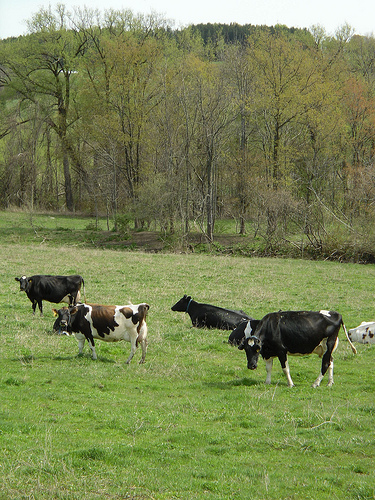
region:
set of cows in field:
[15, 248, 351, 433]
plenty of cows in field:
[8, 248, 355, 426]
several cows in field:
[10, 234, 358, 442]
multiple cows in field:
[6, 228, 347, 413]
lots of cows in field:
[4, 210, 360, 450]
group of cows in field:
[1, 232, 358, 436]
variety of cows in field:
[3, 210, 359, 392]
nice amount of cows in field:
[7, 230, 357, 451]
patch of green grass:
[32, 405, 321, 489]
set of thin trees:
[23, 139, 342, 244]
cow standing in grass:
[66, 301, 153, 364]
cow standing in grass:
[249, 319, 336, 386]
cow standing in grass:
[20, 272, 75, 299]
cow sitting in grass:
[51, 325, 68, 335]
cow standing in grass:
[178, 296, 235, 330]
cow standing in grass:
[234, 319, 250, 335]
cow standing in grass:
[343, 320, 374, 346]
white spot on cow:
[248, 339, 253, 348]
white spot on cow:
[19, 274, 28, 281]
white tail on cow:
[336, 321, 358, 362]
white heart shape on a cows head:
[231, 336, 269, 369]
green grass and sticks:
[196, 391, 350, 493]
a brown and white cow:
[17, 296, 155, 383]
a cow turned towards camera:
[32, 298, 79, 346]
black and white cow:
[224, 300, 344, 408]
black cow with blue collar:
[153, 285, 246, 351]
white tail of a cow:
[338, 313, 362, 378]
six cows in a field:
[3, 271, 373, 380]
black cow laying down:
[148, 286, 241, 349]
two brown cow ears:
[38, 299, 79, 315]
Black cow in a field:
[15, 257, 89, 333]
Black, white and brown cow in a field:
[37, 303, 175, 381]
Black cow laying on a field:
[167, 287, 250, 333]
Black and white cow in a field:
[226, 298, 363, 409]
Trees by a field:
[40, 91, 325, 264]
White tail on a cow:
[326, 307, 362, 369]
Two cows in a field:
[10, 266, 166, 366]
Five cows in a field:
[10, 264, 351, 403]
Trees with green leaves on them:
[48, 51, 295, 267]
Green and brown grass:
[105, 239, 252, 376]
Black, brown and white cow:
[53, 303, 156, 361]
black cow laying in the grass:
[171, 292, 250, 328]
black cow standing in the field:
[16, 274, 85, 305]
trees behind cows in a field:
[8, 7, 371, 260]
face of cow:
[53, 305, 77, 326]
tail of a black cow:
[79, 275, 90, 303]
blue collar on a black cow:
[185, 298, 193, 310]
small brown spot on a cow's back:
[118, 305, 136, 318]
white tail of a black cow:
[340, 315, 359, 356]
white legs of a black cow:
[265, 356, 294, 388]